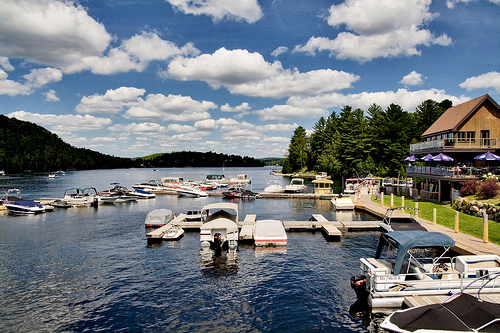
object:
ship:
[141, 208, 178, 228]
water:
[0, 164, 458, 333]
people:
[355, 189, 363, 204]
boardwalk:
[355, 193, 498, 260]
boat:
[221, 186, 264, 200]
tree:
[287, 125, 312, 168]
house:
[404, 93, 499, 206]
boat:
[197, 202, 239, 249]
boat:
[280, 178, 308, 192]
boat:
[347, 229, 499, 333]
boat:
[0, 194, 48, 217]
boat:
[174, 186, 212, 198]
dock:
[257, 192, 348, 201]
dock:
[142, 213, 391, 242]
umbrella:
[471, 148, 499, 165]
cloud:
[164, 0, 267, 27]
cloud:
[394, 69, 425, 88]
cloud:
[160, 0, 266, 25]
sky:
[0, 0, 499, 160]